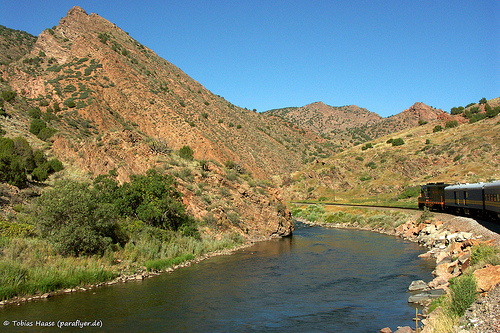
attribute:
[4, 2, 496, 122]
sky — clear, blue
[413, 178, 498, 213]
train — black, red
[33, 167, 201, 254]
bush — large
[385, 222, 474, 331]
stones — colorful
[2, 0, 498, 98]
sky — blue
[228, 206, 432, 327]
river — small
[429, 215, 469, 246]
land — desert, brown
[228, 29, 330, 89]
blue sky — clear, pretty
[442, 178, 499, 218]
passenger cars — blue, orange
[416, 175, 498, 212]
train — moving 